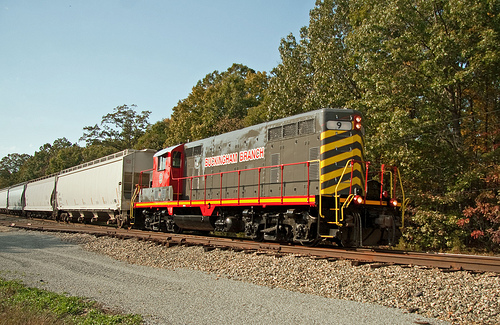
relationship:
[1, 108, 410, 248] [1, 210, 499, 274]
train traveling down tracks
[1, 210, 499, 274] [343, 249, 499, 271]
track has rail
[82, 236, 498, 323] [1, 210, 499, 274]
gravel next to tracks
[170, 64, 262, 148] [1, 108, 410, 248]
tree next to train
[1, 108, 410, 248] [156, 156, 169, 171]
train has window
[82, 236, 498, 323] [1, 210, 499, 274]
gravel alongside tracks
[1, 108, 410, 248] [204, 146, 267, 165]
train has labeling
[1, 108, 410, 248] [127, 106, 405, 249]
train has locomotive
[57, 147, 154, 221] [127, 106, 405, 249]
car behind locomotive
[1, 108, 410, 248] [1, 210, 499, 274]
train riding on tracks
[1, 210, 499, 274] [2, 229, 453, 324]
tracks next to road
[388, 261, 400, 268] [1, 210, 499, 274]
gravel under tracks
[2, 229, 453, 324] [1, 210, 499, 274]
road next to tracks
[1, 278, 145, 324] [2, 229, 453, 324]
grass next to road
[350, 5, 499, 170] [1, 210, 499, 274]
tree next to tracks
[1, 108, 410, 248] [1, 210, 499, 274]
train riding on track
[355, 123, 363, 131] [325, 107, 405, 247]
light mounted on front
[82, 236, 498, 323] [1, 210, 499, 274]
gravel along track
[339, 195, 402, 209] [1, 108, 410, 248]
line on front of train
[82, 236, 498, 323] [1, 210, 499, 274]
gravel along tracks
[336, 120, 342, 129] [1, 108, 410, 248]
9 written on train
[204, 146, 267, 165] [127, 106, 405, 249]
labeling written on side of locomotive